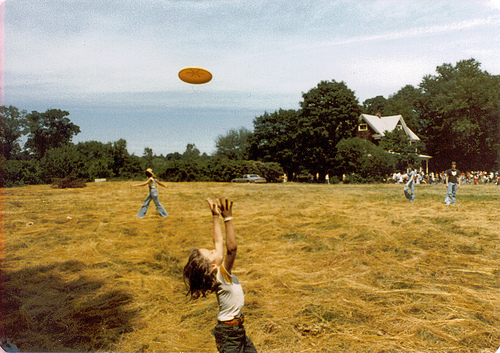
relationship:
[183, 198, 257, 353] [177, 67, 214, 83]
child catching frisbee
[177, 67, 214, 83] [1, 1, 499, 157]
frisbee in sky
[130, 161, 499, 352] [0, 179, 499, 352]
people are playing in field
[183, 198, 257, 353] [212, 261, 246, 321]
child wearing a shirt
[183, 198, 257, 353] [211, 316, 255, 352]
child wearing shorts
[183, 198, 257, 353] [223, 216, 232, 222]
child wearing a wristband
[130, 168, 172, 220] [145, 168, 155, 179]
people wearing a hat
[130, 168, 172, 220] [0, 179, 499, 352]
people walking in field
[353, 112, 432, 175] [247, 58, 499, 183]
house surrounded by trees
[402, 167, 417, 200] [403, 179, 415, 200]
guy wearing jeans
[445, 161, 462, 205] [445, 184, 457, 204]
guy wearing jeans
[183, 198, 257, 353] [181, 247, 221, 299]
child has hair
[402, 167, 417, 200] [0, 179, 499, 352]
guy playing in field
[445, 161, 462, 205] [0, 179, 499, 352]
guy playing in field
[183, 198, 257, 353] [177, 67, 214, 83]
child reaching for frisbee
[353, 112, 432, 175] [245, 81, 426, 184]
house behind trees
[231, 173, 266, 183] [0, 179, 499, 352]
car on field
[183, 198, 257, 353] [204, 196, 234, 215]
child raising her hands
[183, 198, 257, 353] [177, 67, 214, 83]
child trying to catch frisbee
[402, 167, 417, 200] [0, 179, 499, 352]
guy walking in field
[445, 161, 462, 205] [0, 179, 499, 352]
guy walking in field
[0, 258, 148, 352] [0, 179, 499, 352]
shadow on field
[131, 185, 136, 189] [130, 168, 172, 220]
hand on people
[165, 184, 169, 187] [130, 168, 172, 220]
hand on people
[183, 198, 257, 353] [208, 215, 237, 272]
child with arms in air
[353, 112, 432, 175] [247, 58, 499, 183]
house in trees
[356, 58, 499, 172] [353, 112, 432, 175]
trees behind house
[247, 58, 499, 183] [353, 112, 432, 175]
trees by house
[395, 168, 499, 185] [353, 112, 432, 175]
people by house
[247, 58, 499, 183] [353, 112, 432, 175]
trees behind house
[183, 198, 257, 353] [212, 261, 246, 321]
child has a shirt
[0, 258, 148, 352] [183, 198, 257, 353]
shadow behind child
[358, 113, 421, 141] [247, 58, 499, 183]
roof in trees